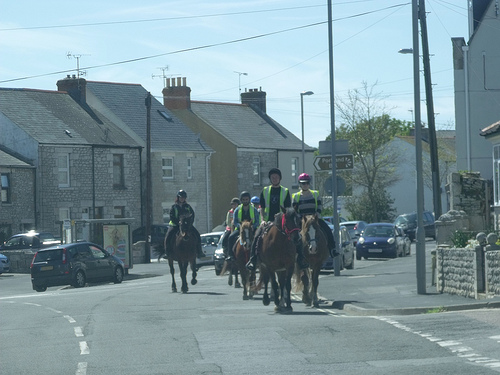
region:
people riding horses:
[144, 151, 353, 325]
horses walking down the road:
[151, 203, 349, 323]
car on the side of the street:
[353, 214, 409, 264]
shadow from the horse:
[183, 279, 223, 297]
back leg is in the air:
[188, 266, 203, 288]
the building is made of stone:
[1, 65, 146, 247]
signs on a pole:
[305, 133, 357, 180]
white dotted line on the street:
[8, 287, 95, 372]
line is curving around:
[5, 292, 101, 369]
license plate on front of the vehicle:
[363, 248, 383, 254]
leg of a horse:
[308, 267, 325, 304]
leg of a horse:
[302, 270, 314, 306]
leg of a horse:
[285, 274, 297, 308]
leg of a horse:
[276, 279, 290, 311]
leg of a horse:
[268, 277, 284, 302]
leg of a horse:
[258, 273, 274, 313]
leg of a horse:
[236, 272, 251, 303]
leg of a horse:
[225, 256, 248, 287]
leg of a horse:
[190, 260, 202, 282]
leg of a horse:
[173, 255, 190, 300]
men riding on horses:
[152, 170, 344, 317]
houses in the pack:
[19, 90, 276, 174]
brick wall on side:
[407, 235, 495, 294]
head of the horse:
[292, 208, 326, 265]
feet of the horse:
[161, 272, 217, 290]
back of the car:
[24, 241, 117, 283]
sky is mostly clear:
[46, 3, 197, 43]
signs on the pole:
[257, 127, 367, 179]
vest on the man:
[253, 163, 288, 214]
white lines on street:
[47, 298, 103, 374]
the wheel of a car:
[68, 263, 91, 290]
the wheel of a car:
[110, 259, 127, 286]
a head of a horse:
[298, 209, 329, 264]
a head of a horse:
[276, 200, 306, 254]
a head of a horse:
[236, 217, 259, 257]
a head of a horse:
[173, 205, 201, 244]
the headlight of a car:
[385, 233, 397, 247]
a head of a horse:
[356, 233, 369, 246]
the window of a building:
[107, 150, 130, 195]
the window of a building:
[157, 150, 178, 185]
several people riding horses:
[155, 173, 328, 313]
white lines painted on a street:
[42, 301, 92, 373]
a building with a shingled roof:
[31, 98, 75, 178]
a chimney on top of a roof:
[154, 60, 196, 120]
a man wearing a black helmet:
[256, 166, 286, 193]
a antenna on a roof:
[226, 62, 251, 104]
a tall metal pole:
[406, 28, 436, 288]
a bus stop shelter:
[60, 211, 136, 252]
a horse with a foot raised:
[185, 255, 199, 290]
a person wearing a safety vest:
[253, 176, 290, 210]